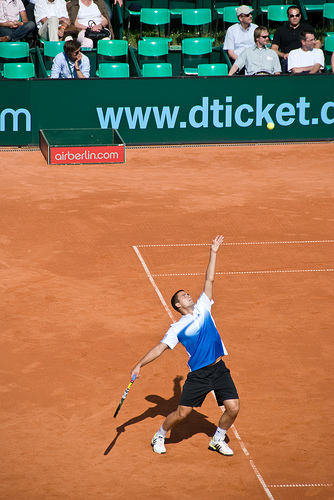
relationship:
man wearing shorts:
[113, 235, 245, 458] [179, 357, 239, 410]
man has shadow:
[113, 235, 245, 458] [97, 375, 225, 446]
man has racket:
[113, 235, 245, 458] [112, 371, 140, 419]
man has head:
[113, 235, 245, 458] [169, 286, 196, 313]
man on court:
[113, 235, 245, 458] [2, 145, 331, 496]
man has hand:
[113, 235, 245, 458] [208, 232, 228, 253]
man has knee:
[113, 235, 245, 458] [222, 394, 247, 424]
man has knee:
[113, 235, 245, 458] [174, 404, 193, 425]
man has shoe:
[113, 235, 245, 458] [148, 423, 171, 455]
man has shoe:
[113, 235, 245, 458] [203, 433, 235, 454]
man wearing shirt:
[113, 235, 245, 458] [163, 293, 231, 374]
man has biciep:
[113, 235, 245, 458] [163, 329, 178, 347]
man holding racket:
[113, 235, 245, 458] [112, 371, 140, 419]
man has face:
[113, 235, 245, 458] [181, 289, 197, 305]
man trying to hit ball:
[113, 235, 245, 458] [265, 117, 276, 132]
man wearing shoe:
[113, 235, 245, 458] [203, 433, 235, 454]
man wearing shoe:
[113, 235, 245, 458] [148, 423, 171, 455]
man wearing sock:
[113, 235, 245, 458] [157, 425, 169, 437]